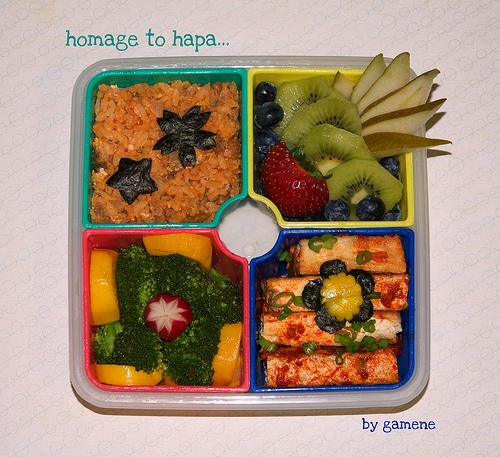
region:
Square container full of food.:
[33, 30, 446, 453]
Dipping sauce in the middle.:
[209, 175, 293, 274]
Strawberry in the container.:
[260, 133, 332, 218]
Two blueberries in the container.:
[254, 79, 284, 132]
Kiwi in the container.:
[269, 63, 396, 188]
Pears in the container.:
[353, 34, 454, 163]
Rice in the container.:
[101, 92, 157, 150]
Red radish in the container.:
[142, 288, 204, 345]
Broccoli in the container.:
[111, 255, 203, 295]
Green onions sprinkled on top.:
[290, 323, 396, 363]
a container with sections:
[59, 37, 457, 367]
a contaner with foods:
[55, 64, 455, 430]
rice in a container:
[32, 44, 495, 439]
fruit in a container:
[105, 23, 432, 300]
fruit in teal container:
[94, 58, 261, 208]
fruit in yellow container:
[240, 61, 385, 223]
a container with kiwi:
[254, 59, 411, 196]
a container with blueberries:
[260, 63, 413, 168]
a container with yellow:
[239, 38, 426, 255]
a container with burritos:
[266, 254, 436, 410]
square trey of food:
[58, 47, 434, 434]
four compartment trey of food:
[63, 51, 405, 421]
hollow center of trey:
[201, 203, 266, 249]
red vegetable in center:
[147, 298, 183, 335]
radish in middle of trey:
[155, 288, 193, 337]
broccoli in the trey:
[197, 273, 230, 318]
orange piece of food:
[75, 245, 123, 320]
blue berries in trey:
[252, 88, 280, 122]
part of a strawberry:
[256, 140, 324, 215]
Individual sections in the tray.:
[86, 67, 416, 392]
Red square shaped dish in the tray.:
[81, 226, 246, 392]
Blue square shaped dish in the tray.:
[245, 225, 412, 391]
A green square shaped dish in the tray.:
[81, 69, 249, 233]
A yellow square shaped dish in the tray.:
[246, 66, 413, 229]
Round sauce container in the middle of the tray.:
[212, 192, 282, 261]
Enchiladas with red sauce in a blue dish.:
[248, 225, 413, 391]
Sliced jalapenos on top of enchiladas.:
[255, 232, 405, 387]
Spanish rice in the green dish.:
[83, 69, 247, 228]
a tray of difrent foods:
[63, 48, 443, 379]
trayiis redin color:
[66, 239, 255, 414]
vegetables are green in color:
[95, 248, 227, 355]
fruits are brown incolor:
[278, 233, 370, 375]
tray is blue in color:
[271, 248, 391, 399]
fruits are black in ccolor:
[301, 96, 399, 218]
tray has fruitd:
[282, 96, 367, 222]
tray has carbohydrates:
[110, 92, 232, 218]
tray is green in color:
[104, 84, 244, 227]